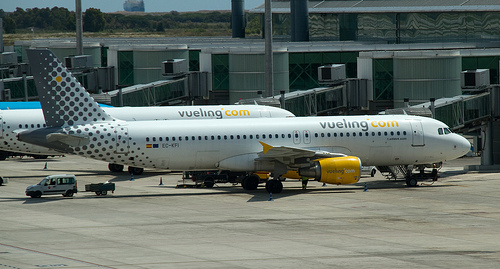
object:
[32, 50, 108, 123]
circle pattern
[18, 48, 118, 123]
airplane tail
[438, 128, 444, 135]
windshield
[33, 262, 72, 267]
writing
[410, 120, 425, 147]
door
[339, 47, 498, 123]
buildings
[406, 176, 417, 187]
tire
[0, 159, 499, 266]
tarmac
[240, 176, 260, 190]
wheels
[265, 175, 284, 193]
landing gear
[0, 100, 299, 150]
plane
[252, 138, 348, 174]
wing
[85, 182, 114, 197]
trailer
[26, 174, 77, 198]
snow suit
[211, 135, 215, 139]
window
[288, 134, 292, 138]
window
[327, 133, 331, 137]
window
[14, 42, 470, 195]
airplane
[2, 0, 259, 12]
sky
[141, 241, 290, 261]
square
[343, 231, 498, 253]
square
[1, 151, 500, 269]
ground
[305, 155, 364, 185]
engine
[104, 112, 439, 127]
back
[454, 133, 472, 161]
nose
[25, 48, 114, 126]
stabilizer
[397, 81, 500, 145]
ramp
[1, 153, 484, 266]
pavement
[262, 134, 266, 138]
window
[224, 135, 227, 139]
window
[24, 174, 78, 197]
car